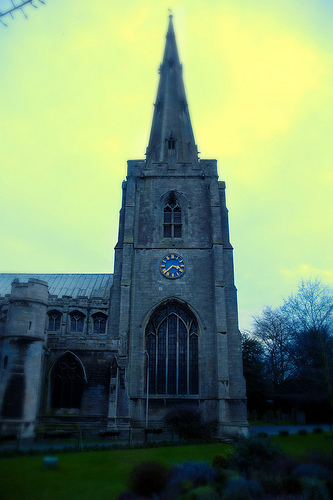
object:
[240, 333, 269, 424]
trees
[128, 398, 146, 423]
concrete block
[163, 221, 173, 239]
windows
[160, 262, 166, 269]
roman numerals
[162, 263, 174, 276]
hands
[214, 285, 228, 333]
block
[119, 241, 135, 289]
block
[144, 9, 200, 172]
spire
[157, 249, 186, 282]
clock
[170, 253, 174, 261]
numbers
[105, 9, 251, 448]
tower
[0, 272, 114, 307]
roof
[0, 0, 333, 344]
glow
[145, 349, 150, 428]
drain pipe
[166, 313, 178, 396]
glass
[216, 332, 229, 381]
block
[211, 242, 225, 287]
block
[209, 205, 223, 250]
block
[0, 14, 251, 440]
building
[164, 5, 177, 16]
statue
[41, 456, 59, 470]
item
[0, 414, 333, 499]
ground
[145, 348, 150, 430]
light post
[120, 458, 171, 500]
bush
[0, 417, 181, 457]
gate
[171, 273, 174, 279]
numbers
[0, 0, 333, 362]
sky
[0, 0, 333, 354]
clouds